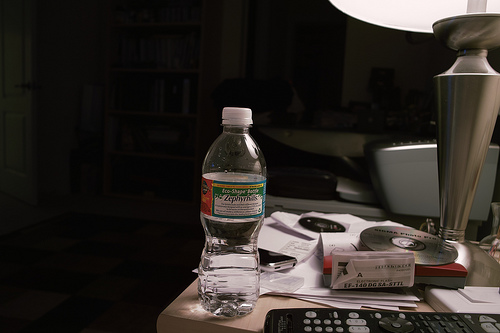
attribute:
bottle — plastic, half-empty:
[195, 96, 269, 323]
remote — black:
[265, 305, 498, 331]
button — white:
[342, 314, 371, 326]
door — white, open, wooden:
[3, 5, 39, 204]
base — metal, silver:
[427, 14, 500, 295]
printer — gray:
[354, 132, 498, 241]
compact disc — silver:
[356, 221, 466, 271]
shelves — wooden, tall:
[98, 1, 220, 211]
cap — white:
[218, 106, 252, 127]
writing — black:
[369, 226, 441, 243]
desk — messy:
[155, 166, 498, 330]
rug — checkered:
[0, 209, 211, 329]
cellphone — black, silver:
[255, 247, 297, 272]